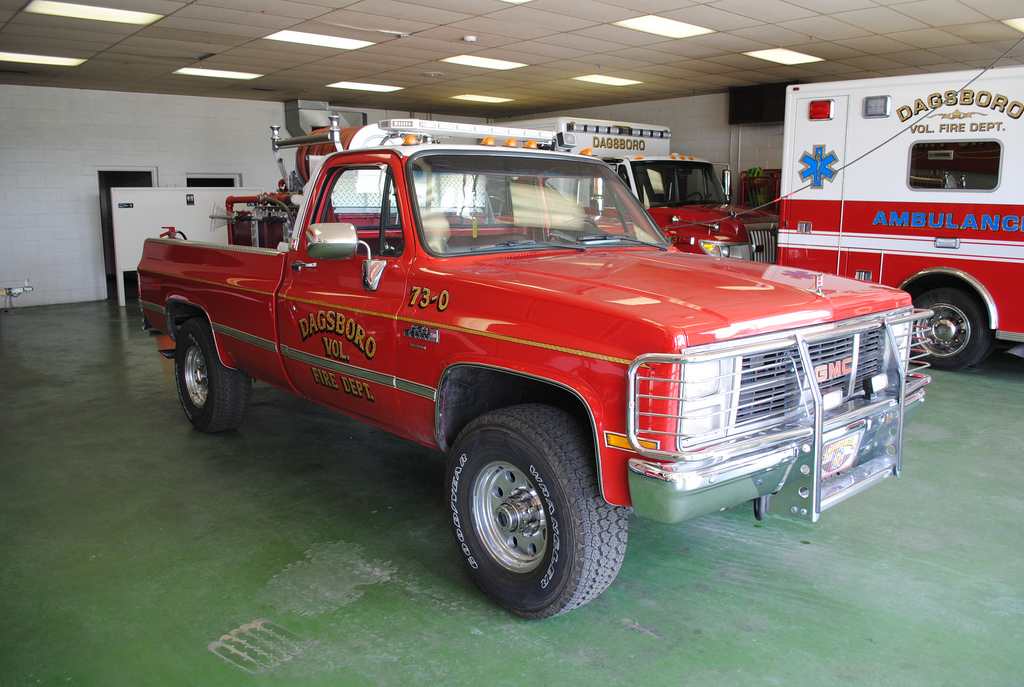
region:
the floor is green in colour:
[124, 461, 246, 532]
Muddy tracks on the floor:
[103, 492, 516, 683]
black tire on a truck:
[442, 393, 633, 627]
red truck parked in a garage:
[126, 130, 937, 621]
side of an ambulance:
[783, 64, 1022, 365]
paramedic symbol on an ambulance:
[795, 143, 841, 192]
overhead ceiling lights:
[43, 14, 715, 104]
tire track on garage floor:
[180, 595, 320, 676]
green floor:
[35, 437, 206, 666]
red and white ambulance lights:
[805, 93, 894, 119]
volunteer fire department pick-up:
[134, 136, 928, 620]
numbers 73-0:
[403, 276, 451, 314]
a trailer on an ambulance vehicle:
[755, 68, 1019, 287]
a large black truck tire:
[427, 390, 637, 609]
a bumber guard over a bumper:
[676, 321, 968, 525]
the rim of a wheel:
[476, 447, 553, 564]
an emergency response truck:
[152, 70, 949, 571]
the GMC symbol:
[776, 351, 893, 418]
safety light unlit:
[345, 127, 627, 204]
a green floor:
[122, 462, 470, 679]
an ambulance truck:
[749, 77, 1009, 387]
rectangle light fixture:
[243, 0, 421, 99]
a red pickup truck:
[123, 118, 943, 593]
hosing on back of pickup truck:
[288, 127, 416, 191]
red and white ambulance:
[796, 78, 1022, 326]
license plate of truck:
[821, 437, 888, 464]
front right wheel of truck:
[460, 400, 631, 667]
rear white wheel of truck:
[182, 315, 233, 426]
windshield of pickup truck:
[423, 167, 673, 253]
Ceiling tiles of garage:
[300, 0, 719, 90]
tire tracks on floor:
[177, 565, 387, 683]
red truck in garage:
[147, 85, 961, 654]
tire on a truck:
[439, 370, 632, 647]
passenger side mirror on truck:
[294, 212, 387, 295]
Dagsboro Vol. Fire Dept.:
[284, 284, 393, 414]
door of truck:
[287, 148, 409, 443]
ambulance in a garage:
[770, 67, 1011, 397]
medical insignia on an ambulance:
[790, 131, 849, 209]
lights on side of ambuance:
[795, 92, 907, 132]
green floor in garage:
[47, 387, 428, 678]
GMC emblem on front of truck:
[801, 336, 858, 404]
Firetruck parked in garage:
[60, 102, 968, 625]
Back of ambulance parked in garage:
[752, 64, 1022, 257]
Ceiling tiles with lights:
[40, 4, 824, 78]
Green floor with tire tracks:
[85, 481, 421, 677]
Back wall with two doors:
[12, 101, 254, 326]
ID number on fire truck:
[391, 272, 464, 327]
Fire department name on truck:
[278, 300, 393, 419]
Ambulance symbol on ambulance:
[792, 136, 844, 197]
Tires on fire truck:
[151, 278, 626, 629]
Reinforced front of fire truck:
[599, 262, 938, 537]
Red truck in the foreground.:
[146, 144, 912, 570]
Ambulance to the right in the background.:
[782, 75, 1020, 327]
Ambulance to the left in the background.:
[554, 106, 778, 249]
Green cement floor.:
[98, 481, 364, 681]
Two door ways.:
[84, 154, 254, 314]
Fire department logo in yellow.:
[283, 299, 400, 420]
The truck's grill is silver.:
[625, 302, 931, 459]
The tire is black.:
[435, 391, 649, 621]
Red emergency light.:
[804, 90, 844, 135]